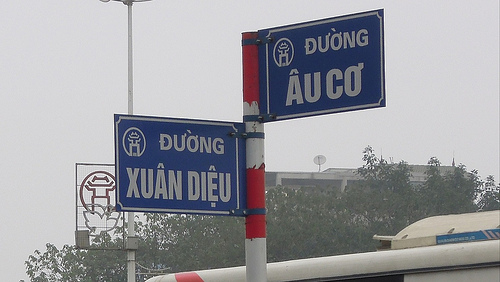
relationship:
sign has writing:
[115, 114, 247, 216] [127, 131, 233, 204]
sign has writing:
[261, 9, 386, 123] [284, 27, 368, 107]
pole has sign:
[242, 34, 268, 279] [115, 114, 247, 216]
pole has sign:
[242, 34, 268, 279] [261, 9, 386, 123]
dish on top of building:
[313, 153, 329, 173] [268, 165, 475, 230]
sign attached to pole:
[115, 114, 247, 216] [242, 34, 268, 279]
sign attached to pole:
[261, 9, 386, 123] [242, 34, 268, 279]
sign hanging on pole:
[115, 114, 247, 216] [242, 34, 268, 279]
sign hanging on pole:
[261, 9, 386, 123] [242, 34, 268, 279]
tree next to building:
[364, 148, 497, 250] [268, 165, 475, 230]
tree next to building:
[267, 179, 383, 262] [268, 165, 475, 230]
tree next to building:
[143, 213, 246, 279] [268, 165, 475, 230]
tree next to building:
[19, 212, 127, 278] [268, 165, 475, 230]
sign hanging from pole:
[115, 114, 247, 216] [242, 34, 268, 279]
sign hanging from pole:
[261, 9, 386, 123] [242, 34, 268, 279]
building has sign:
[268, 165, 475, 230] [115, 114, 247, 216]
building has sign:
[268, 165, 475, 230] [261, 9, 386, 123]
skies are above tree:
[5, 5, 496, 279] [364, 148, 497, 250]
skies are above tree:
[5, 5, 496, 279] [267, 179, 383, 262]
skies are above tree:
[5, 5, 496, 279] [143, 213, 246, 279]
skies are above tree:
[5, 5, 496, 279] [19, 212, 127, 278]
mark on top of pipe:
[176, 270, 203, 279] [148, 239, 497, 280]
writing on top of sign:
[127, 131, 233, 204] [115, 114, 247, 216]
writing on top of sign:
[284, 27, 368, 107] [261, 9, 386, 123]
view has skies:
[5, 3, 494, 275] [5, 5, 496, 279]